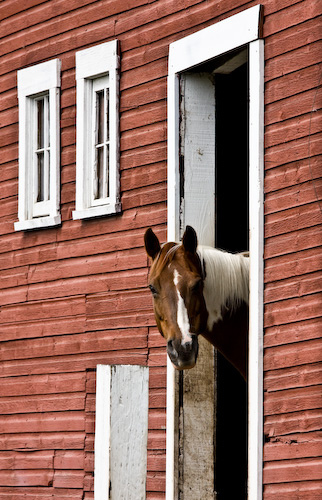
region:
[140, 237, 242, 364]
this is the horse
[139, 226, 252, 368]
the horse is brown in color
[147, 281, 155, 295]
this is the eye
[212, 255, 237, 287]
the fur is white in color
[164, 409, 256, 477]
the window is open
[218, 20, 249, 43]
the frame is white in color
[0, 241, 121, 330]
the wall is brown in color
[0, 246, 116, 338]
the wall is wooden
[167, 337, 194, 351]
this is the nose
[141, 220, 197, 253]
these are the two ears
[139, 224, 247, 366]
Horse's head sticking out an opening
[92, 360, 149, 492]
White pole in front of building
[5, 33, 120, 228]
Two windows of the building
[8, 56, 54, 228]
White window on the left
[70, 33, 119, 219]
White window on the right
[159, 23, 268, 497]
White opening of building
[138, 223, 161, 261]
Horse's right ear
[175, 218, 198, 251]
Horse's left ear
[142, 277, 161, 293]
Horse's right eye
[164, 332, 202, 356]
Horse's black nose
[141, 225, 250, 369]
a brown and white horse looking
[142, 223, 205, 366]
the head of a horse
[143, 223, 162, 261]
the brown ear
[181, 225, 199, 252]
the brown ear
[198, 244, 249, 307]
the white mane of the horse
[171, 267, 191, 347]
the white stripe on the head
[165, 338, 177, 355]
the large nostril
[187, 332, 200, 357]
the large nostril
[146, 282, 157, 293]
the black eye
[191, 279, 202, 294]
the black eye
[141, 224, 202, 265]
ears on a horse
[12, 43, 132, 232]
white windows on a barn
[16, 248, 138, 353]
the red wood siding of a barn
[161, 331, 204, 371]
the nose and mouth of a horse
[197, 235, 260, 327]
the white mane of a horse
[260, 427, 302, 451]
decayed wood siding on a barn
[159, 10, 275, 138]
white trim around the door of a barn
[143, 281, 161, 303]
an eye on a horse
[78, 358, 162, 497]
a white post outside a barn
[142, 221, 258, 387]
this is a horse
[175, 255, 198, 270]
the fur is brown in color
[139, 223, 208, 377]
this is the horse's head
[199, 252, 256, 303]
hair on the horse's head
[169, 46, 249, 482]
this is a door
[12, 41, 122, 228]
these are two windows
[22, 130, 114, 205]
the windows are closed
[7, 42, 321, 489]
this is a building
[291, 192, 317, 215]
the wall is brown in color